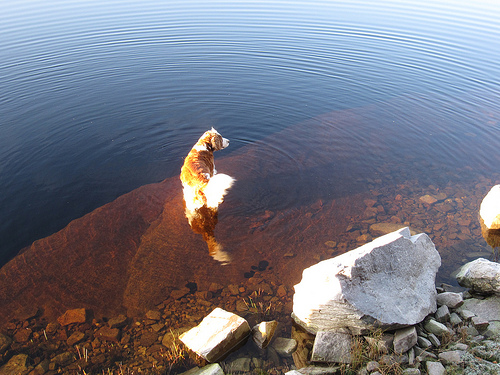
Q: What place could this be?
A: It is a shore.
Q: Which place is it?
A: It is a shore.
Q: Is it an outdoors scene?
A: Yes, it is outdoors.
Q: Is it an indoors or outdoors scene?
A: It is outdoors.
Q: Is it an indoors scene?
A: No, it is outdoors.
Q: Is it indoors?
A: No, it is outdoors.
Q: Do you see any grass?
A: Yes, there is grass.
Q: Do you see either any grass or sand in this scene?
A: Yes, there is grass.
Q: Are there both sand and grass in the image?
A: No, there is grass but no sand.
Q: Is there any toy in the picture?
A: No, there are no toys.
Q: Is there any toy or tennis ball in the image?
A: No, there are no toys or tennis balls.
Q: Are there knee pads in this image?
A: No, there are no knee pads.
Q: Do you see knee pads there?
A: No, there are no knee pads.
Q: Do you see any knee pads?
A: No, there are no knee pads.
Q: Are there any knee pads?
A: No, there are no knee pads.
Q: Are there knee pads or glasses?
A: No, there are no knee pads or glasses.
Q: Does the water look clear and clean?
A: Yes, the water is clear and clean.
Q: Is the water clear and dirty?
A: No, the water is clear but clean.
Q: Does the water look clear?
A: Yes, the water is clear.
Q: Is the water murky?
A: No, the water is clear.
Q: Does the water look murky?
A: No, the water is clear.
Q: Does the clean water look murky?
A: No, the water is clear.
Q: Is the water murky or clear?
A: The water is clear.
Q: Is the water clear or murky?
A: The water is clear.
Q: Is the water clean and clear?
A: Yes, the water is clean and clear.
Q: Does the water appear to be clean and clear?
A: Yes, the water is clean and clear.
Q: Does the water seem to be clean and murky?
A: No, the water is clean but clear.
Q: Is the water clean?
A: Yes, the water is clean.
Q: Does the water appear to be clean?
A: Yes, the water is clean.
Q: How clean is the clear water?
A: The water is clean.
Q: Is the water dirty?
A: No, the water is clean.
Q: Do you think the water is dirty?
A: No, the water is clean.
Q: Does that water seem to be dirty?
A: No, the water is clean.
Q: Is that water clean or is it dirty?
A: The water is clean.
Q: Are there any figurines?
A: No, there are no figurines.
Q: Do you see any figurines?
A: No, there are no figurines.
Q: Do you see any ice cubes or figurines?
A: No, there are no figurines or ice cubes.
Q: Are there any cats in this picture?
A: No, there are no cats.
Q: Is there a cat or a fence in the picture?
A: No, there are no cats or fences.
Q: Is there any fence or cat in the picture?
A: No, there are no cats or fences.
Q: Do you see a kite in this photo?
A: No, there are no kites.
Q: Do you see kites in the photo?
A: No, there are no kites.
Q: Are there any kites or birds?
A: No, there are no kites or birds.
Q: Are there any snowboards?
A: No, there are no snowboards.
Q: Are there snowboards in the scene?
A: No, there are no snowboards.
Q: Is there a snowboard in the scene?
A: No, there are no snowboards.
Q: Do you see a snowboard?
A: No, there are no snowboards.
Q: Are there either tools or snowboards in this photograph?
A: No, there are no snowboards or tools.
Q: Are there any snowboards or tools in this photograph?
A: No, there are no snowboards or tools.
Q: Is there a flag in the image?
A: No, there are no flags.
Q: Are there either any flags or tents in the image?
A: No, there are no flags or tents.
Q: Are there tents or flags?
A: No, there are no flags or tents.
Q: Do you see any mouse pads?
A: No, there are no mouse pads.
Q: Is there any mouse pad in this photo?
A: No, there are no mouse pads.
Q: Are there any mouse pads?
A: No, there are no mouse pads.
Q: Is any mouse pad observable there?
A: No, there are no mouse pads.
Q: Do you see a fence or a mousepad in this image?
A: No, there are no mouse pads or fences.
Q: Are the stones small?
A: Yes, the stones are small.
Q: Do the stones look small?
A: Yes, the stones are small.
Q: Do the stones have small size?
A: Yes, the stones are small.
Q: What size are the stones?
A: The stones are small.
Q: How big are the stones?
A: The stones are small.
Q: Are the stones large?
A: No, the stones are small.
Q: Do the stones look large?
A: No, the stones are small.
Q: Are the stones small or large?
A: The stones are small.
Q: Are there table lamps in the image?
A: No, there are no table lamps.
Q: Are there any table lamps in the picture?
A: No, there are no table lamps.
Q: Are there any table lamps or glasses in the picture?
A: No, there are no table lamps or glasses.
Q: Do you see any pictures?
A: No, there are no pictures.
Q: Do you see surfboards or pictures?
A: No, there are no pictures or surfboards.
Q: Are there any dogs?
A: Yes, there is a dog.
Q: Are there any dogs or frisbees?
A: Yes, there is a dog.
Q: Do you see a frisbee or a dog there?
A: Yes, there is a dog.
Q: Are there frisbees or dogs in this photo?
A: Yes, there is a dog.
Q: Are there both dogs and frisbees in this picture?
A: No, there is a dog but no frisbees.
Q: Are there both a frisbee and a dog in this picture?
A: No, there is a dog but no frisbees.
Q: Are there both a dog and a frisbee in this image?
A: No, there is a dog but no frisbees.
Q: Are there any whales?
A: No, there are no whales.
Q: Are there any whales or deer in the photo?
A: No, there are no whales or deer.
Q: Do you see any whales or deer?
A: No, there are no whales or deer.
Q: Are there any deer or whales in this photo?
A: No, there are no whales or deer.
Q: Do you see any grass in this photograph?
A: Yes, there is grass.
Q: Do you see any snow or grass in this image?
A: Yes, there is grass.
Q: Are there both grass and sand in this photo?
A: No, there is grass but no sand.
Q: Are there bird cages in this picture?
A: No, there are no bird cages.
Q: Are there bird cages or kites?
A: No, there are no bird cages or kites.